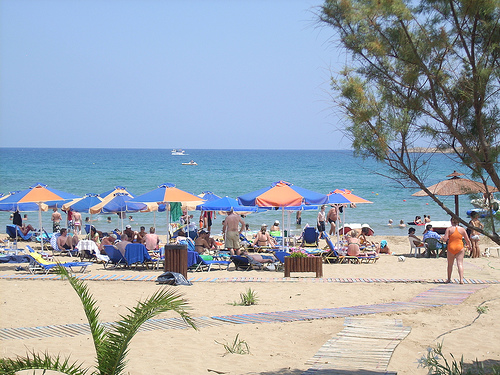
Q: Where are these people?
A: Beach.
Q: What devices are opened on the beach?
A: Umbrellas.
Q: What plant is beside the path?
A: Palm fronds.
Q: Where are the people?
A: The people at the beach.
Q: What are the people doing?
A: The people are relaxing.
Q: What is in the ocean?
A: A boat.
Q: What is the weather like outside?
A: The weather is hot.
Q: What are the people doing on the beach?
A: They are relaxing.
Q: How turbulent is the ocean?
A: The water is calm.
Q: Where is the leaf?
A: On the tree.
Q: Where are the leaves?
A: On the trees.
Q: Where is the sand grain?
A: On the beach.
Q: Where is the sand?
A: On the beach.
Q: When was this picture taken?
A: During the day.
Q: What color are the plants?
A: Green.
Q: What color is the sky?
A: Blue.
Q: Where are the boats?
A: Out in the ocean.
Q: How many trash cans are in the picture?
A: One.